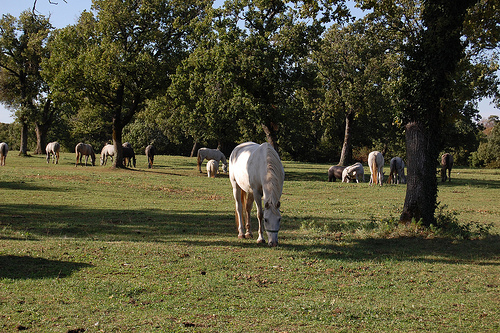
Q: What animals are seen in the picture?
A: Horses.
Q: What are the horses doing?
A: Grazing on grass.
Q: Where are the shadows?
A: The shadows are seen on the grass.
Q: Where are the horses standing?
A: Field of grass.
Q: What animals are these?
A: Horses.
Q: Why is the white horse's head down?
A: Eating grass.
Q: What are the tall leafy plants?
A: Trees.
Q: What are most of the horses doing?
A: Grazing.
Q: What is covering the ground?
A: Grass.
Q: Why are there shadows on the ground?
A: Sun is shining.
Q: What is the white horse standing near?
A: Tree.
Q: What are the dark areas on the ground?
A: Shadows.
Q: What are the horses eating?
A: Grass.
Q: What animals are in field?
A: White horses.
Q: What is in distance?
A: Large green tree.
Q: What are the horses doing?
A: Eating grass.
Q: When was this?
A: Daytime.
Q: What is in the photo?
A: Horses.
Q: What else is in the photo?
A: Trees.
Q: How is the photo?
A: Clear.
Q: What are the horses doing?
A: Grazing.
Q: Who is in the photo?
A: Nobody.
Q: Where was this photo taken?
A: In a pasture.